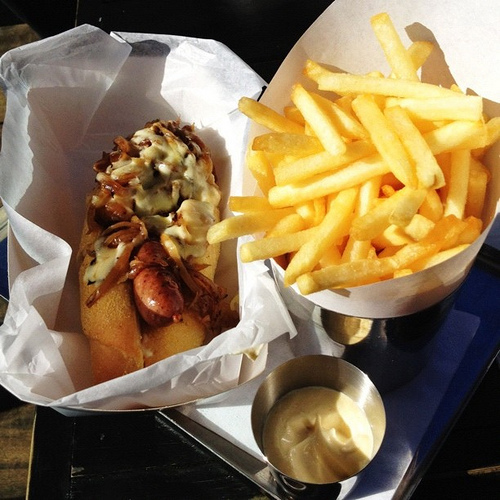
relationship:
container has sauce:
[249, 355, 388, 499] [263, 386, 376, 484]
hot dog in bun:
[133, 267, 184, 326] [79, 205, 220, 388]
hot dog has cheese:
[133, 267, 184, 326] [83, 119, 221, 286]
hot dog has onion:
[133, 267, 184, 326] [86, 116, 227, 317]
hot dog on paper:
[133, 267, 184, 326] [0, 22, 300, 409]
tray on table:
[154, 213, 500, 499] [2, 294, 39, 498]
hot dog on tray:
[133, 267, 184, 326] [154, 213, 500, 499]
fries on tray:
[206, 11, 500, 298] [154, 213, 500, 499]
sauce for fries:
[263, 386, 376, 484] [206, 11, 500, 298]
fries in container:
[206, 11, 500, 298] [243, 0, 500, 318]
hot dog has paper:
[133, 267, 184, 326] [0, 22, 300, 409]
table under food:
[2, 294, 39, 498] [76, 13, 493, 485]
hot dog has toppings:
[133, 267, 184, 326] [79, 118, 230, 322]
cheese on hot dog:
[83, 119, 221, 286] [133, 267, 184, 326]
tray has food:
[154, 213, 500, 499] [76, 13, 493, 485]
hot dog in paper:
[133, 267, 184, 326] [0, 22, 300, 409]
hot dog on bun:
[133, 267, 184, 326] [79, 205, 220, 388]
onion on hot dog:
[86, 116, 227, 317] [133, 267, 184, 326]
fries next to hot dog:
[206, 11, 500, 298] [133, 267, 184, 326]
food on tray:
[76, 13, 493, 485] [154, 213, 500, 499]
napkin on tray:
[174, 333, 295, 462] [154, 213, 500, 499]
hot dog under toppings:
[133, 267, 184, 326] [79, 118, 230, 322]